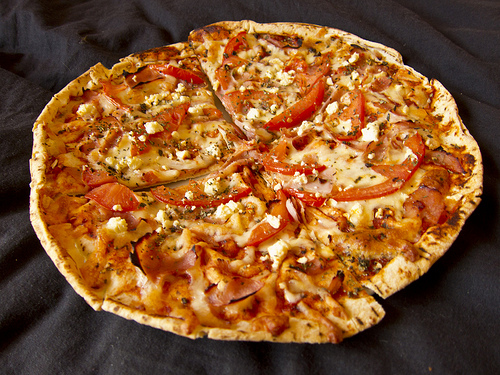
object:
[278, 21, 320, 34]
edge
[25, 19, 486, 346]
pizza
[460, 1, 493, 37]
part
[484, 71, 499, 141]
cloth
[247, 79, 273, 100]
part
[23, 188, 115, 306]
side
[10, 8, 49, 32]
sheet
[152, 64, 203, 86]
tomato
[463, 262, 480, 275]
part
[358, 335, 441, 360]
duvet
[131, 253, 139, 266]
black mark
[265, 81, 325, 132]
tomatoes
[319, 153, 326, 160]
cheese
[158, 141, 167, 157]
black and green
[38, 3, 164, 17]
blanket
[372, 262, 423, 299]
crust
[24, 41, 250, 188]
slices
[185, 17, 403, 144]
slice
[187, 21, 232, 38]
crust edge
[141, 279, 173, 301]
prosciutto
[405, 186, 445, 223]
ham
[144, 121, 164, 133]
feta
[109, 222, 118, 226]
goat cheese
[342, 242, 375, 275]
oregano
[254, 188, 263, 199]
toppings